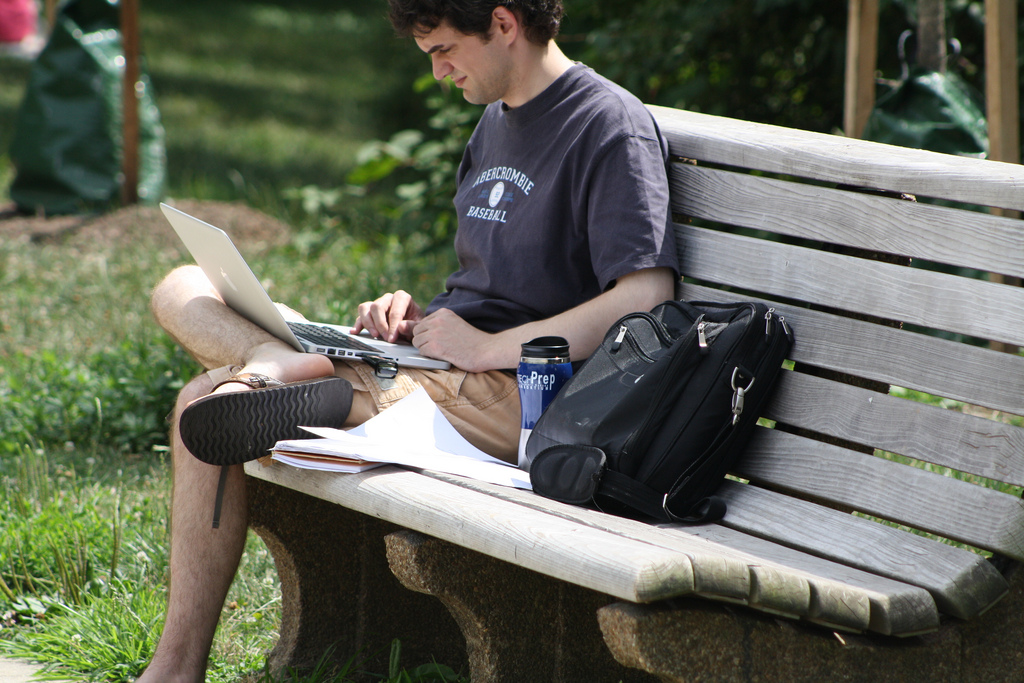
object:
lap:
[158, 202, 453, 371]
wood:
[243, 455, 697, 603]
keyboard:
[285, 322, 383, 354]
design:
[465, 166, 534, 222]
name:
[466, 206, 507, 223]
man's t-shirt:
[424, 64, 681, 330]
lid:
[158, 203, 308, 354]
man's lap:
[336, 359, 523, 466]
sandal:
[178, 376, 353, 467]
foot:
[210, 353, 334, 395]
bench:
[243, 102, 1023, 638]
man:
[143, 0, 679, 682]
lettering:
[517, 371, 555, 391]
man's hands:
[350, 290, 493, 373]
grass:
[0, 228, 455, 681]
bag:
[525, 301, 796, 526]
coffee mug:
[517, 336, 574, 473]